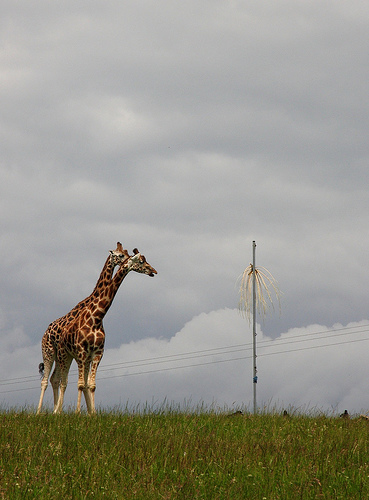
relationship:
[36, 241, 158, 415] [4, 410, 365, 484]
body standing in field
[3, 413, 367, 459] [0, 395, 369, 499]
grass covering grass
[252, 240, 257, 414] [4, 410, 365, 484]
metal pole in field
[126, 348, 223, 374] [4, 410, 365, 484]
electric lines hanging over field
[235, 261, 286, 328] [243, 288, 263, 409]
hay attached metal pole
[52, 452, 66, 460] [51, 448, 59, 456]
seeds on stem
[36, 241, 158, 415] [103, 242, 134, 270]
body has head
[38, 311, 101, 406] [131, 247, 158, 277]
giraffe has head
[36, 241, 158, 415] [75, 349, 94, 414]
body has leg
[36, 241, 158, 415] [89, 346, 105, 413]
body has leg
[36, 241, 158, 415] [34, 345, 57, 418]
body has leg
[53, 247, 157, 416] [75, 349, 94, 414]
giraffe has leg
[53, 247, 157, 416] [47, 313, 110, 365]
giraffe has body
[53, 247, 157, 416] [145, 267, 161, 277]
giraffe has mouth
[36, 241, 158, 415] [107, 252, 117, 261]
body has ear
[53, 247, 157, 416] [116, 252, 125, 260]
giraffe has eye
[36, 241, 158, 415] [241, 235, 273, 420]
body eyeing pole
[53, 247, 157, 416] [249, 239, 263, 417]
giraffe eyeing pole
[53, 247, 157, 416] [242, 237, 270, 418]
giraffe eyeing pole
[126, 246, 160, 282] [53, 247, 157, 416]
head on giraffe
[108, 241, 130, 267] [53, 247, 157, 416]
head on giraffe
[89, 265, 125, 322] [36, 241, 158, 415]
neck on body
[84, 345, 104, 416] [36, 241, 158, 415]
leg on body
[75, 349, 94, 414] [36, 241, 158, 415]
leg on body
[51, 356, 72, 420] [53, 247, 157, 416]
leg on giraffe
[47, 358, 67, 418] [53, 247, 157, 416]
leg on giraffe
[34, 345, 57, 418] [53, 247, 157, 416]
leg on giraffe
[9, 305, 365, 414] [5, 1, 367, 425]
clouds in sky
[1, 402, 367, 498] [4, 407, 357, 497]
grass in field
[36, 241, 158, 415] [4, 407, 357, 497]
body in field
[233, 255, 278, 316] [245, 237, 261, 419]
hay hanging from pole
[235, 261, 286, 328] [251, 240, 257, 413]
hay hanging from pole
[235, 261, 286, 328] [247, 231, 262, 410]
hay hanging from pole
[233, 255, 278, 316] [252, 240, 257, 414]
hay hanging from metal pole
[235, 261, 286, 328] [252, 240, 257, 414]
hay hanging from metal pole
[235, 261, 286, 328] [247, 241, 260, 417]
hay hanging from pole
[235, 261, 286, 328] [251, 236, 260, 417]
hay hanging from pole